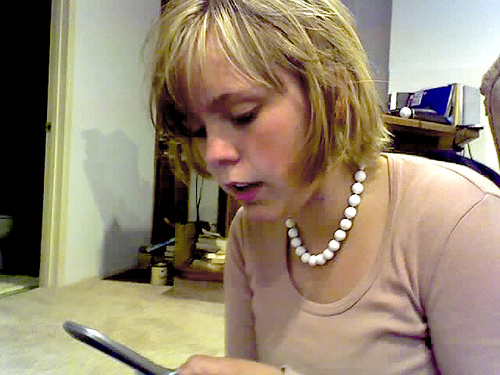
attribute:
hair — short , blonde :
[148, 2, 391, 189]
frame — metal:
[40, 1, 65, 293]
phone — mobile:
[18, 316, 158, 366]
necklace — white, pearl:
[283, 156, 365, 266]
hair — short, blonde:
[148, 3, 392, 154]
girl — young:
[129, 1, 499, 374]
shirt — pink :
[217, 146, 499, 373]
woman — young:
[157, 0, 499, 374]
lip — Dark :
[231, 186, 263, 200]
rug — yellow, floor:
[115, 261, 193, 326]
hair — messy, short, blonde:
[316, 47, 361, 110]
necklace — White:
[251, 159, 375, 280]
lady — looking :
[130, 21, 449, 373]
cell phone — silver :
[56, 310, 180, 373]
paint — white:
[331, 0, 494, 174]